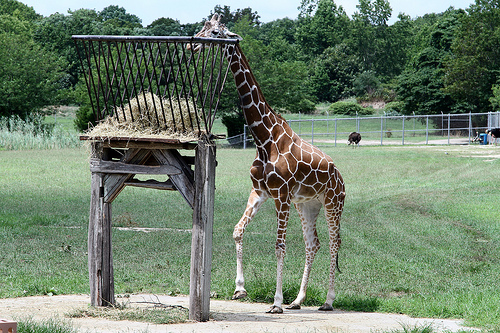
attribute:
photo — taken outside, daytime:
[0, 1, 497, 332]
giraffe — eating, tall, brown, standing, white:
[185, 13, 346, 313]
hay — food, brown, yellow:
[83, 90, 209, 143]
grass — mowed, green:
[4, 148, 495, 333]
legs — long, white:
[231, 188, 352, 316]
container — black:
[68, 35, 239, 137]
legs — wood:
[89, 141, 218, 322]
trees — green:
[1, 2, 499, 135]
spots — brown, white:
[193, 23, 346, 288]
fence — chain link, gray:
[218, 110, 499, 149]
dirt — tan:
[1, 292, 487, 332]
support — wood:
[78, 134, 218, 322]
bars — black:
[72, 39, 237, 135]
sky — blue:
[17, 1, 476, 28]